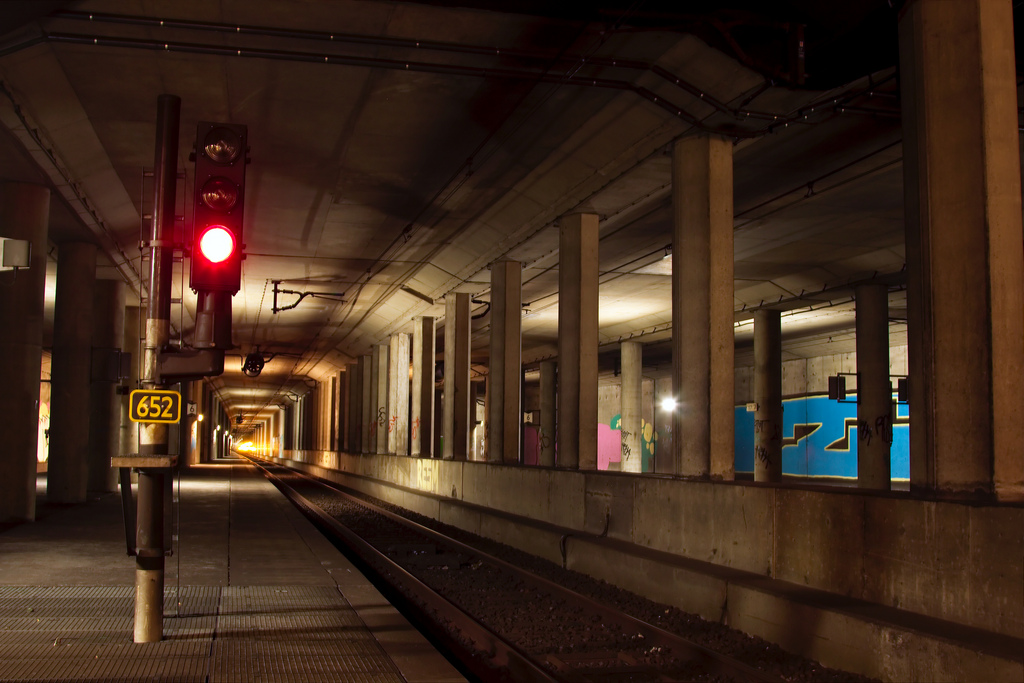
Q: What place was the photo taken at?
A: It was taken at the train station.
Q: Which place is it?
A: It is a train station.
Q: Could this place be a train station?
A: Yes, it is a train station.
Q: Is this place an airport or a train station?
A: It is a train station.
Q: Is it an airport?
A: No, it is a train station.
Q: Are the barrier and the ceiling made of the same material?
A: Yes, both the barrier and the ceiling are made of concrete.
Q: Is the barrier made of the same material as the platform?
A: Yes, both the barrier and the platform are made of concrete.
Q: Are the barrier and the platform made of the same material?
A: Yes, both the barrier and the platform are made of concrete.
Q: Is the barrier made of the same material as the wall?
A: Yes, both the barrier and the wall are made of cement.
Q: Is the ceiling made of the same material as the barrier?
A: Yes, both the ceiling and the barrier are made of cement.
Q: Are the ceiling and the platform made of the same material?
A: Yes, both the ceiling and the platform are made of cement.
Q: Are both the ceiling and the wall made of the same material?
A: Yes, both the ceiling and the wall are made of concrete.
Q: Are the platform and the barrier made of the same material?
A: Yes, both the platform and the barrier are made of cement.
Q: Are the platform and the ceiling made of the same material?
A: Yes, both the platform and the ceiling are made of cement.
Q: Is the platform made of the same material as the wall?
A: Yes, both the platform and the wall are made of cement.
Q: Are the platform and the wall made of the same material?
A: Yes, both the platform and the wall are made of cement.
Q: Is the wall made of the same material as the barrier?
A: Yes, both the wall and the barrier are made of concrete.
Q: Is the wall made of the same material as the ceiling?
A: Yes, both the wall and the ceiling are made of cement.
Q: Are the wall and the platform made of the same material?
A: Yes, both the wall and the platform are made of cement.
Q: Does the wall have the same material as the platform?
A: Yes, both the wall and the platform are made of cement.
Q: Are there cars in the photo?
A: No, there are no cars.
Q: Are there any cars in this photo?
A: No, there are no cars.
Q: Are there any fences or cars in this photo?
A: No, there are no cars or fences.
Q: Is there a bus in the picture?
A: No, there are no buses.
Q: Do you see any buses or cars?
A: No, there are no buses or cars.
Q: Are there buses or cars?
A: No, there are no buses or cars.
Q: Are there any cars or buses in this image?
A: No, there are no buses or cars.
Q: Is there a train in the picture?
A: Yes, there is a train.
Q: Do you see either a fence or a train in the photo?
A: Yes, there is a train.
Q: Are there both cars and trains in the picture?
A: No, there is a train but no cars.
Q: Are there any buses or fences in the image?
A: No, there are no fences or buses.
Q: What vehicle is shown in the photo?
A: The vehicle is a train.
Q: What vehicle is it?
A: The vehicle is a train.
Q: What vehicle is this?
A: That is a train.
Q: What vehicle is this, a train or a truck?
A: That is a train.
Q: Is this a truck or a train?
A: This is a train.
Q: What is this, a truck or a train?
A: This is a train.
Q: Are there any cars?
A: No, there are no cars.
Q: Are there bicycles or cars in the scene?
A: No, there are no cars or bicycles.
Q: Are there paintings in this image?
A: No, there are no paintings.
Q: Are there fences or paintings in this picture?
A: No, there are no paintings or fences.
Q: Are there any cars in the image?
A: No, there are no cars.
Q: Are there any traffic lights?
A: Yes, there is a traffic light.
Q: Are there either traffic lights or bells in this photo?
A: Yes, there is a traffic light.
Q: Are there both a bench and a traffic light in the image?
A: No, there is a traffic light but no benches.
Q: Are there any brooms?
A: No, there are no brooms.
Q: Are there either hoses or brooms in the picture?
A: No, there are no brooms or hoses.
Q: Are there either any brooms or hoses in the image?
A: No, there are no brooms or hoses.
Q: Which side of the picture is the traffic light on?
A: The traffic light is on the left of the image.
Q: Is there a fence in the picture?
A: No, there are no fences.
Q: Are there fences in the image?
A: No, there are no fences.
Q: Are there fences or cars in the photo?
A: No, there are no fences or cars.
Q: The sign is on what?
A: The sign is on the pole.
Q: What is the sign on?
A: The sign is on the pole.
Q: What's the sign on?
A: The sign is on the pole.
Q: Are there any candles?
A: No, there are no candles.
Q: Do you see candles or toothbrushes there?
A: No, there are no candles or toothbrushes.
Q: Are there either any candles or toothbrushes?
A: No, there are no candles or toothbrushes.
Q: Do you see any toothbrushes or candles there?
A: No, there are no candles or toothbrushes.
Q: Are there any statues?
A: No, there are no statues.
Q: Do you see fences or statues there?
A: No, there are no statues or fences.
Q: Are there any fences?
A: No, there are no fences.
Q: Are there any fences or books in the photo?
A: No, there are no fences or books.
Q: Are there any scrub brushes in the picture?
A: No, there are no scrub brushes.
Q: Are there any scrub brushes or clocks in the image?
A: No, there are no scrub brushes or clocks.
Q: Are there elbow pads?
A: No, there are no elbow pads.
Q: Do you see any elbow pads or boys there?
A: No, there are no elbow pads or boys.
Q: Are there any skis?
A: No, there are no skis.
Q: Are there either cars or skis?
A: No, there are no skis or cars.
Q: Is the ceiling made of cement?
A: Yes, the ceiling is made of cement.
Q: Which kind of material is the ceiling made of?
A: The ceiling is made of cement.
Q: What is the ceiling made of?
A: The ceiling is made of concrete.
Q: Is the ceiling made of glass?
A: No, the ceiling is made of concrete.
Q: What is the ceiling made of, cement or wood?
A: The ceiling is made of cement.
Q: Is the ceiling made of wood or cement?
A: The ceiling is made of cement.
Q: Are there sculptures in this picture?
A: No, there are no sculptures.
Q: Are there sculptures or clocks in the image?
A: No, there are no sculptures or clocks.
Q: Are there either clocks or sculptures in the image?
A: No, there are no sculptures or clocks.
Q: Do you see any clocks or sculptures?
A: No, there are no sculptures or clocks.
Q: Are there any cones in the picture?
A: No, there are no cones.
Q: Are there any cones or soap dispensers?
A: No, there are no cones or soap dispensers.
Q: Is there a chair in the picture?
A: No, there are no chairs.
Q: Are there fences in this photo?
A: No, there are no fences.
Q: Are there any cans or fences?
A: No, there are no fences or cans.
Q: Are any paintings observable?
A: No, there are no paintings.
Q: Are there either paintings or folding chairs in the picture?
A: No, there are no paintings or folding chairs.